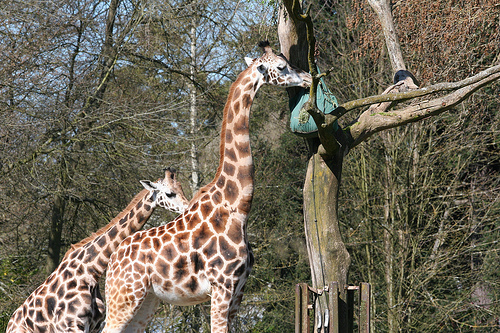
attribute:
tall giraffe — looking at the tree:
[99, 38, 312, 329]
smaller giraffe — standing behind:
[5, 164, 193, 330]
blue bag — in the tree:
[290, 52, 335, 137]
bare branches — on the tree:
[391, 131, 484, 261]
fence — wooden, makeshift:
[294, 280, 372, 330]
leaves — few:
[342, 1, 498, 85]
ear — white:
[139, 177, 161, 192]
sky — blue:
[0, 0, 278, 162]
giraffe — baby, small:
[7, 167, 189, 331]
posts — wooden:
[294, 280, 372, 330]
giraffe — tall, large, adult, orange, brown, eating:
[102, 40, 312, 329]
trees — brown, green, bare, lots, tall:
[0, 1, 498, 331]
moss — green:
[274, 1, 496, 329]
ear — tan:
[136, 176, 160, 191]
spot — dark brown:
[190, 219, 213, 248]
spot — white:
[169, 238, 178, 245]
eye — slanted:
[275, 64, 289, 74]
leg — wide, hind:
[100, 252, 150, 331]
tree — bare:
[0, 1, 240, 329]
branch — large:
[97, 1, 120, 89]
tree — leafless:
[4, 0, 177, 309]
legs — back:
[102, 294, 238, 330]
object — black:
[395, 65, 417, 86]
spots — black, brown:
[142, 221, 240, 282]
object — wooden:
[294, 280, 373, 330]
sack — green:
[289, 71, 338, 133]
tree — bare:
[21, 17, 119, 291]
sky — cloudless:
[14, 2, 273, 87]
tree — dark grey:
[300, 147, 355, 330]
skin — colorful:
[127, 235, 221, 286]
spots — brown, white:
[130, 242, 238, 285]